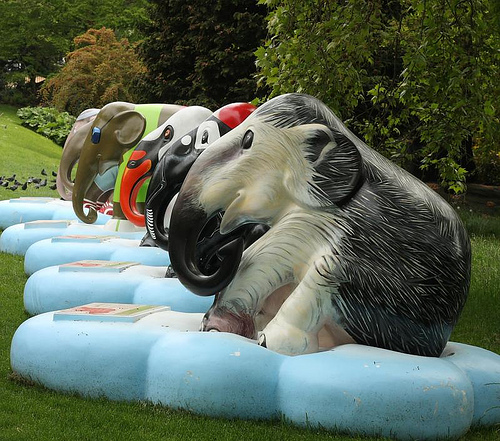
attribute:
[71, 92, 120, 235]
elephant — statue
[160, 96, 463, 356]
statue — elephant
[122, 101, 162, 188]
torso — green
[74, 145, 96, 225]
green trunk — dark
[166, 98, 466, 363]
elephant — grey, white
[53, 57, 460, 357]
elephants — stone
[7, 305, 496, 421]
base — blue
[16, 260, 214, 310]
base — blue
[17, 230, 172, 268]
base — blue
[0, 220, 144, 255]
base — blue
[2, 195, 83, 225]
base — blue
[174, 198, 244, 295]
trunk — black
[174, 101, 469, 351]
elephant statue — black, white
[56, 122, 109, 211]
statute — elephant, last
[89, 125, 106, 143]
strip — blue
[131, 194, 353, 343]
trunks — black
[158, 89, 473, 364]
statute — elephant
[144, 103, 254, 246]
statute — elephant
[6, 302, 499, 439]
stone — blue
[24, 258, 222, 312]
stone — blue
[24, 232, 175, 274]
stone — blue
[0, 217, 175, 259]
stone — blue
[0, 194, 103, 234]
stone — blue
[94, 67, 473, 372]
trunk — red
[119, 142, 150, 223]
trunk — red